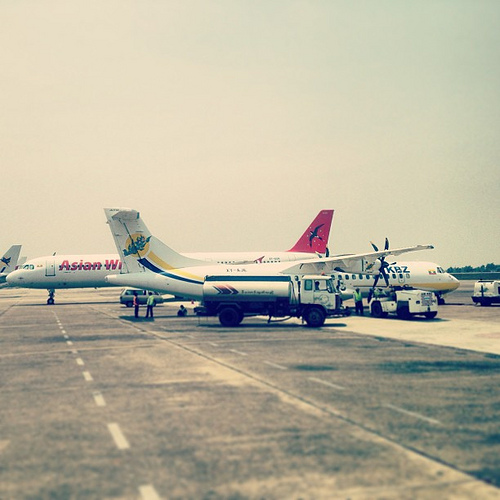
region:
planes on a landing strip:
[3, 198, 468, 334]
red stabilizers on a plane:
[289, 202, 336, 255]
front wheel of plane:
[41, 284, 58, 307]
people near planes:
[101, 255, 193, 330]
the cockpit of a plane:
[423, 261, 461, 290]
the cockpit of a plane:
[6, 253, 44, 295]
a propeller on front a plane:
[363, 235, 398, 292]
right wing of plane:
[296, 240, 438, 265]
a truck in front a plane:
[196, 262, 347, 329]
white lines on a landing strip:
[36, 295, 171, 497]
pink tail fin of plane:
[281, 205, 335, 255]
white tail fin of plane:
[98, 203, 152, 270]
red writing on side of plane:
[52, 258, 118, 276]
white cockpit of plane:
[5, 255, 43, 282]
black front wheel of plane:
[38, 296, 60, 311]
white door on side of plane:
[43, 252, 56, 279]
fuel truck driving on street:
[209, 271, 297, 300]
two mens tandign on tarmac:
[126, 288, 158, 325]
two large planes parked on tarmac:
[3, 223, 456, 308]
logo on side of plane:
[210, 279, 278, 299]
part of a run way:
[408, 419, 425, 445]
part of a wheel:
[226, 310, 230, 317]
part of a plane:
[419, 270, 422, 273]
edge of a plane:
[397, 263, 399, 268]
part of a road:
[310, 412, 329, 444]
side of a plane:
[148, 253, 160, 275]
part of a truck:
[322, 289, 332, 316]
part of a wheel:
[310, 305, 316, 312]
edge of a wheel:
[224, 300, 237, 320]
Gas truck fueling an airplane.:
[185, 272, 363, 330]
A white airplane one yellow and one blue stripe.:
[101, 205, 456, 299]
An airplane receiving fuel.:
[100, 205, 456, 302]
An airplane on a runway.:
[100, 205, 456, 315]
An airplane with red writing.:
[5, 247, 115, 297]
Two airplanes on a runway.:
[10, 207, 461, 288]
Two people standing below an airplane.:
[130, 289, 157, 314]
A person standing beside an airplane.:
[352, 285, 362, 312]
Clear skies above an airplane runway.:
[17, 11, 474, 203]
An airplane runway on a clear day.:
[17, 336, 482, 483]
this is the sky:
[231, 52, 278, 94]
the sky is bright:
[343, 44, 447, 159]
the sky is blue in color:
[302, 118, 419, 160]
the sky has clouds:
[213, 172, 284, 225]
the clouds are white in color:
[17, 151, 65, 201]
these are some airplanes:
[24, 214, 449, 316]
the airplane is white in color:
[213, 252, 228, 259]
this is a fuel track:
[200, 271, 342, 324]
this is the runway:
[196, 366, 285, 441]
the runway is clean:
[195, 433, 280, 479]